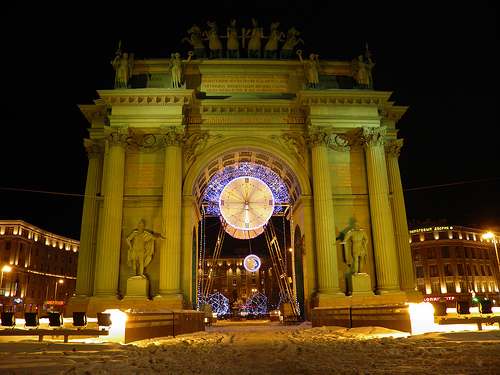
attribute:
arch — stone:
[182, 137, 311, 195]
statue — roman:
[124, 218, 163, 302]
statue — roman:
[340, 217, 373, 300]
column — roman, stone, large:
[158, 140, 185, 303]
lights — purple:
[201, 162, 294, 214]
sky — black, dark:
[2, 1, 499, 217]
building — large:
[67, 18, 436, 334]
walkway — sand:
[1, 322, 500, 375]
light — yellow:
[481, 229, 495, 242]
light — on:
[55, 277, 66, 286]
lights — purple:
[208, 291, 227, 312]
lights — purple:
[248, 289, 270, 311]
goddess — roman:
[109, 54, 130, 92]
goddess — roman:
[349, 46, 379, 85]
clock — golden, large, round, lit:
[213, 172, 278, 239]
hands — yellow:
[226, 179, 254, 206]